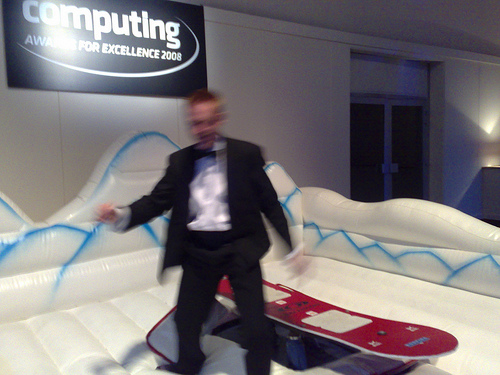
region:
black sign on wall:
[5, 0, 203, 110]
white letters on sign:
[13, 1, 183, 66]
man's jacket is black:
[143, 146, 305, 241]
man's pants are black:
[180, 248, 283, 368]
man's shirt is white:
[180, 153, 242, 228]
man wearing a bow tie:
[183, 133, 225, 172]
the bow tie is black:
[182, 133, 237, 182]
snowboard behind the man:
[198, 235, 480, 372]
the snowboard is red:
[188, 230, 400, 367]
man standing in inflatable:
[123, 84, 335, 359]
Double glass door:
[352, 78, 432, 222]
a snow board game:
[161, 231, 463, 363]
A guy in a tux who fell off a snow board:
[78, 69, 471, 374]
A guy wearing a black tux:
[91, 76, 319, 373]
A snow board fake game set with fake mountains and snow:
[3, 101, 499, 371]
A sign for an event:
[7, 0, 214, 113]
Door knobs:
[376, 156, 405, 180]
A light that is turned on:
[473, 112, 498, 184]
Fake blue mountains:
[327, 221, 394, 267]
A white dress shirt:
[178, 145, 247, 242]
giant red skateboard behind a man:
[198, 250, 458, 367]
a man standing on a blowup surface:
[101, 92, 306, 371]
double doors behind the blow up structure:
[346, 86, 434, 207]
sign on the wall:
[3, 1, 208, 99]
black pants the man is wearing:
[177, 228, 271, 374]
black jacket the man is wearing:
[124, 137, 291, 281]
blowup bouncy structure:
[2, 118, 499, 374]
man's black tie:
[190, 146, 220, 160]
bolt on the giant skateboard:
[374, 325, 389, 336]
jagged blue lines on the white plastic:
[302, 219, 495, 291]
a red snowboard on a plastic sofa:
[229, 268, 457, 359]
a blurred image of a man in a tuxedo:
[99, 90, 295, 374]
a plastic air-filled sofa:
[1, 191, 96, 373]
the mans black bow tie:
[193, 148, 220, 160]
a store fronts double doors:
[348, 52, 429, 200]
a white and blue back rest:
[303, 185, 498, 295]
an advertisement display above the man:
[2, 0, 208, 97]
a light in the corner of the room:
[446, 56, 498, 211]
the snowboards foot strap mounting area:
[302, 308, 372, 334]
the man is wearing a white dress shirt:
[190, 156, 232, 233]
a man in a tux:
[130, 40, 298, 297]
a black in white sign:
[32, 8, 194, 80]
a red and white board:
[203, 265, 466, 358]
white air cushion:
[5, 277, 106, 369]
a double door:
[317, 54, 457, 214]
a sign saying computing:
[19, 4, 201, 46]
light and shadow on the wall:
[447, 78, 498, 155]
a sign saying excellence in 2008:
[105, 39, 187, 73]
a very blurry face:
[152, 81, 279, 163]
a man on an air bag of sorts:
[72, 90, 418, 373]